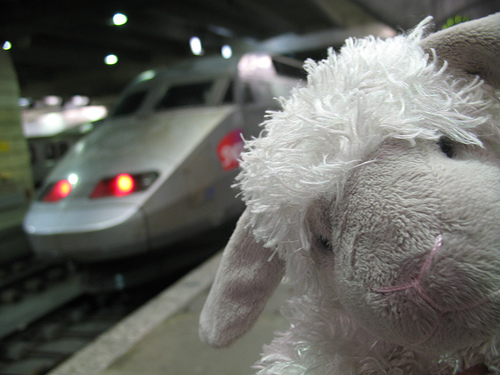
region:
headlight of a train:
[108, 181, 135, 192]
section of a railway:
[61, 300, 102, 334]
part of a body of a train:
[180, 163, 198, 187]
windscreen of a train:
[176, 92, 197, 102]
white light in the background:
[106, 59, 117, 64]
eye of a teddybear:
[443, 147, 455, 152]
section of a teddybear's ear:
[228, 257, 257, 313]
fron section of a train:
[39, 234, 110, 247]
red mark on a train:
[225, 145, 242, 163]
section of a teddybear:
[317, 317, 356, 356]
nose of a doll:
[400, 266, 436, 303]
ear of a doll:
[207, 290, 253, 321]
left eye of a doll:
[433, 124, 458, 166]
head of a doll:
[334, 145, 397, 212]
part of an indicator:
[101, 172, 149, 212]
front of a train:
[41, 212, 124, 254]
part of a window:
[178, 85, 223, 107]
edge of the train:
[168, 131, 223, 163]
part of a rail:
[67, 318, 97, 342]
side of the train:
[231, 87, 262, 117]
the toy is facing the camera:
[200, 18, 496, 369]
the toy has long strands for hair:
[234, 15, 485, 245]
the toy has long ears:
[194, 204, 305, 347]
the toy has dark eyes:
[315, 230, 335, 256]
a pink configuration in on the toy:
[371, 238, 498, 353]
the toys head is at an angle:
[195, 23, 497, 373]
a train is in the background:
[21, 52, 311, 262]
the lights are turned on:
[38, 174, 150, 201]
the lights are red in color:
[51, 172, 135, 198]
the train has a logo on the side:
[213, 126, 260, 172]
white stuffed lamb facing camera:
[190, 21, 494, 371]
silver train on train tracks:
[12, 42, 317, 277]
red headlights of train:
[29, 165, 158, 207]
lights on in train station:
[87, 7, 145, 32]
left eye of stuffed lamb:
[418, 131, 464, 167]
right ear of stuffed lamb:
[182, 193, 286, 352]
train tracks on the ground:
[7, 273, 87, 369]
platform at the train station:
[84, 299, 195, 373]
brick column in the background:
[2, 71, 34, 240]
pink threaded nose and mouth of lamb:
[363, 229, 496, 355]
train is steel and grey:
[36, 53, 326, 248]